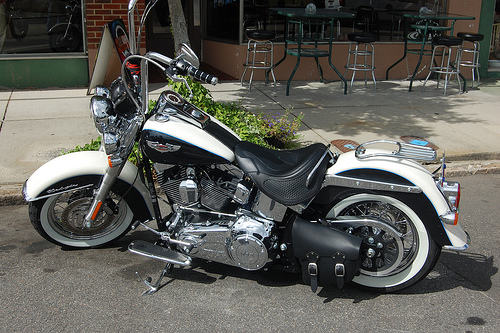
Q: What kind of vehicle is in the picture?
A: A motorcycle.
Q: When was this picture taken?
A: During the day.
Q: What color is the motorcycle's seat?
A: Black.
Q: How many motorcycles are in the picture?
A: One.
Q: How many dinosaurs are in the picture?
A: Zero.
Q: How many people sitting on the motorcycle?
A: Zero.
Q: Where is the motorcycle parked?
A: In the street.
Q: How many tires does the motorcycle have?
A: Two.